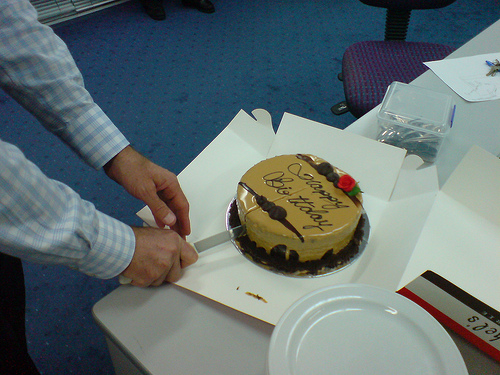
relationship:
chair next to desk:
[329, 0, 474, 127] [88, 18, 495, 370]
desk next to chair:
[88, 18, 495, 370] [329, 0, 474, 127]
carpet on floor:
[0, 3, 427, 372] [3, 1, 498, 369]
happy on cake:
[290, 160, 351, 215] [236, 155, 363, 258]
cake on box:
[230, 149, 368, 256] [108, 103, 498, 356]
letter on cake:
[318, 190, 338, 205] [233, 148, 380, 280]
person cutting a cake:
[0, 1, 195, 372] [226, 152, 374, 280]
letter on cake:
[283, 160, 318, 180] [228, 148, 370, 273]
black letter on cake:
[303, 218, 339, 233] [231, 151, 364, 268]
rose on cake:
[336, 172, 355, 192] [231, 151, 364, 268]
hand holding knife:
[114, 221, 242, 294] [173, 214, 270, 282]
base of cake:
[227, 200, 372, 275] [231, 151, 364, 268]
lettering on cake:
[267, 160, 350, 218] [193, 117, 381, 294]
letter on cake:
[268, 157, 343, 231] [226, 152, 374, 280]